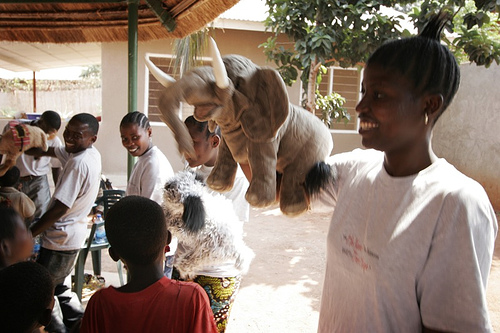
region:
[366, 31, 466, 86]
black hair on a head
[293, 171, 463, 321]
a grey tee shirt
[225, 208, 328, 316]
a shadow on the ground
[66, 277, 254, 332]
a red tee shirt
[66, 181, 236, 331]
a little boy with back turned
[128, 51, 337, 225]
a grey stuffed elephant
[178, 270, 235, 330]
a very colorful garmet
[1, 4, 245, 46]
a brown awning above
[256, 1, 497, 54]
some green leaves on tree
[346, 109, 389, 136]
white teeth in a mouth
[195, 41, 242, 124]
White tusk on elephant.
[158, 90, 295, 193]
Gray stuffed animal puppet.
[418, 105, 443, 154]
Earrings on woman's ear.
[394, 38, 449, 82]
Woman has black hair.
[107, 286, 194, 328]
Person wearing red shirt.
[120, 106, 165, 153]
Person has black hair.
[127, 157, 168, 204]
Person wearing gray shirt.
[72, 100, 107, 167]
Person has short black hair.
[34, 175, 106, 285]
Person wearing gray shirt.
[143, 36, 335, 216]
the stuffed elephant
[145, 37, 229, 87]
the tusks on the elephant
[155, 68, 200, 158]
the trunk on the elephant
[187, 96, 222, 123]
the mouth on the elephant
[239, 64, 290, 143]
the ear on the elephant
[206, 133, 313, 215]
the legs on the elephant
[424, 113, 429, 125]
the earring in the woman's ear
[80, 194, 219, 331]
the small child standing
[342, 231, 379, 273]
the words on the woman's shirt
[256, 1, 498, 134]
the green leaves on the tree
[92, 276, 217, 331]
the shirt is red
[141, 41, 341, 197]
the elephant has horns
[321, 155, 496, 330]
the shirt is white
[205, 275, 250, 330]
the lesso is yellow and blue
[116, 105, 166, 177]
the woman has braids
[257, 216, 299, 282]
shadow is on the ground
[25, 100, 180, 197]
the people are smiling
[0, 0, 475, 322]
the people are in africa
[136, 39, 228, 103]
the tasks are white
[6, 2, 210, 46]
the umbrella is made of glass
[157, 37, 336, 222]
stuffed puppet gray elephant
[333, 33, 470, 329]
african american woman smiling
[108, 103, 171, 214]
African American very happy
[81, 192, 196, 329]
Young african american child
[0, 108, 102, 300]
African american male having a good time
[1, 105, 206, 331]
Childs party where everyone is having fun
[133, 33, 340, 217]
greay stuffed elephant with tusks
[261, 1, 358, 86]
tree in the background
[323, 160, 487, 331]
grey or white t-shirt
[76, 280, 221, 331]
read over sized t-shirt